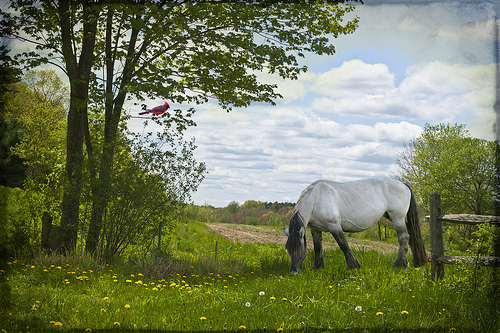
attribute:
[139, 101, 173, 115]
bird — red, cardinal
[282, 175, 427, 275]
horse — standing, grazing, gray, black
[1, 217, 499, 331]
grass — green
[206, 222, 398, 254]
road — dirt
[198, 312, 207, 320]
flower — yellow, little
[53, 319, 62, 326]
flower — yellow, little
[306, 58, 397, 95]
cloud — white, puffy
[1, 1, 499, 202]
sky — blue, cloudy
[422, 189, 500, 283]
fence — wooden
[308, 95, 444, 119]
cloud — fluffy, white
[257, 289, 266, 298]
dandelion — white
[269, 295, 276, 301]
dandelion — yellow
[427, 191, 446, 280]
post — wooden, end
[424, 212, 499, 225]
rail — top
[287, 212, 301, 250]
mane — black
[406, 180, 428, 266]
tail — long, black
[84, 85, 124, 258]
trunk — thin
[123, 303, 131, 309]
flower — yellow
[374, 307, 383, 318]
flower — yellow